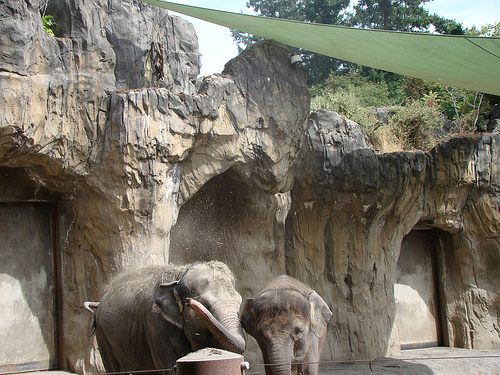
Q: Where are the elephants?
A: On the dirt.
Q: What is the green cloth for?
A: Shade.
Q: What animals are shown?
A: Elephant.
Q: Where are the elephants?
A: In a zoo pen.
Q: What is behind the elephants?
A: A rock wall.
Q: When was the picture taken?
A: During daylight hours.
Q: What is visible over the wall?
A: Trees.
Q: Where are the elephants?
A: In the shade.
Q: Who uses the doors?
A: Zookeepers.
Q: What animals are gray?
A: Elephants.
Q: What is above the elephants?
A: A canopy.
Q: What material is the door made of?
A: Metal.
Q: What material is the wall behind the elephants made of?
A: Rock.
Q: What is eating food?
A: Elephants.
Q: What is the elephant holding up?
A: It's trunk.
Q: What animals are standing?
A: Elephants.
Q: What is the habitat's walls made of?
A: Rock.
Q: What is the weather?
A: Sunny.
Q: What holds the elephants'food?
A: A bucket.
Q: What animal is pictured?
A: Elephants.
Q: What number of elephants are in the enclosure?
A: 2.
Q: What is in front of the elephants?
A: A fence.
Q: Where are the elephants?
A: Behind the fence.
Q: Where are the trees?
A: Behind the rocks.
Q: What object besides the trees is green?
A: The canopy.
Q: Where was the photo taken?
A: Zoo.